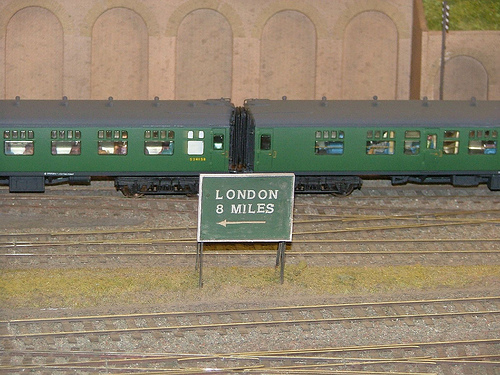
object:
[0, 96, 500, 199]
train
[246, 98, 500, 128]
roof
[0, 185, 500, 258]
track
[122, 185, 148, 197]
wheel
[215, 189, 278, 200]
lettering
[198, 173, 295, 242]
sign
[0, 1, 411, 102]
wall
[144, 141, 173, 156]
window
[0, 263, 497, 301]
grass